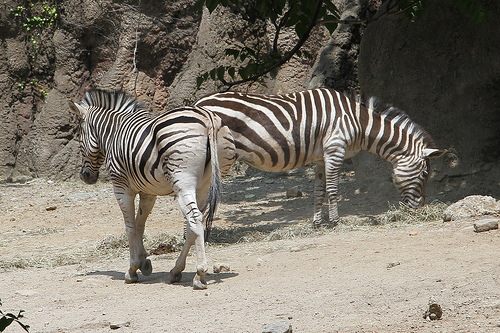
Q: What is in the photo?
A: Zebras.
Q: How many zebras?
A: 2.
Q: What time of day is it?
A: Day time.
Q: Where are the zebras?
A: Zoo.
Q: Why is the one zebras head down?
A: Eating.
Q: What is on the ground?
A: Rocks.